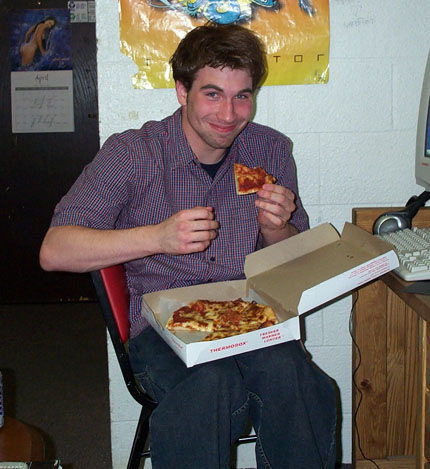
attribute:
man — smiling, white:
[39, 26, 341, 468]